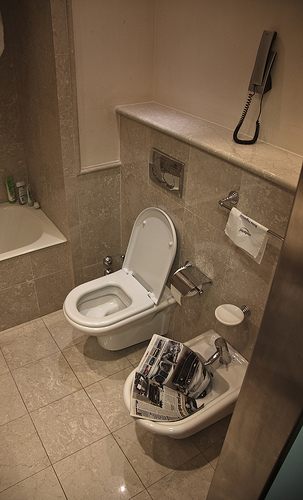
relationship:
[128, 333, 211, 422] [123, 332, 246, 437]
magazine in bowl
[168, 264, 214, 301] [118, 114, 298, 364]
roll of toilet paper on wall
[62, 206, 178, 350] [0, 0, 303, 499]
toilet in bathroom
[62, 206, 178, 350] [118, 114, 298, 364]
toilet hanging on wall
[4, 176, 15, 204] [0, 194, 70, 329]
bottle on bathtub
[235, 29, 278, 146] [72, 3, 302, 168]
phone on wall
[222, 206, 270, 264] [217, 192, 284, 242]
bag on towel rack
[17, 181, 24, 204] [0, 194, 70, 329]
bottle on bathtub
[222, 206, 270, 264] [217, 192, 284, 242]
bag resting on towel rack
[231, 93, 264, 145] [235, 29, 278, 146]
cord of phone